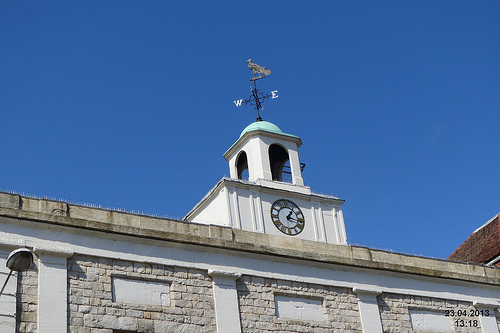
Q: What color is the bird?
A: Gray.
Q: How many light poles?
A: One.